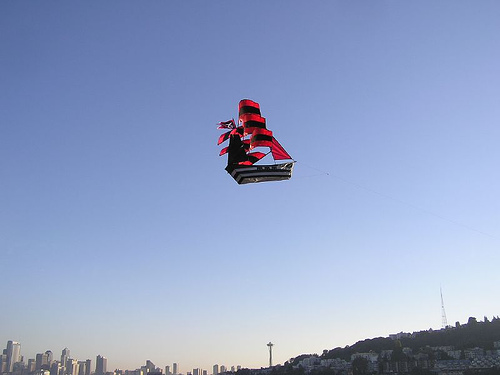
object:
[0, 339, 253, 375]
building building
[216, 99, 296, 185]
kite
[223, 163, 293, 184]
boat base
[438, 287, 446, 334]
radio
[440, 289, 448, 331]
tower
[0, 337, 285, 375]
skyline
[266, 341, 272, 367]
light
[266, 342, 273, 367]
tower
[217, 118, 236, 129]
flag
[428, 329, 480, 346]
bushes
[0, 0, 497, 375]
blue skies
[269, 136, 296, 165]
sail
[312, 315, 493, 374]
houses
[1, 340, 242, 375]
city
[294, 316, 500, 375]
hill